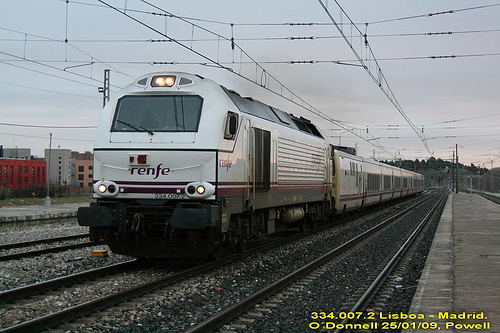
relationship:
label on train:
[126, 158, 171, 180] [72, 62, 433, 267]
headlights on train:
[181, 175, 211, 204] [72, 62, 433, 267]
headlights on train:
[93, 183, 121, 202] [72, 62, 433, 267]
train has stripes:
[72, 62, 433, 267] [218, 176, 255, 197]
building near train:
[40, 146, 77, 191] [72, 62, 433, 267]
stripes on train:
[218, 176, 255, 197] [72, 62, 433, 267]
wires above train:
[70, 18, 464, 73] [72, 62, 433, 267]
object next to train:
[82, 242, 112, 261] [72, 62, 433, 267]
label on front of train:
[126, 158, 171, 180] [72, 62, 433, 267]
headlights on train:
[146, 73, 174, 87] [72, 62, 433, 267]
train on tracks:
[72, 62, 433, 267] [20, 260, 170, 322]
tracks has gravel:
[20, 260, 170, 322] [75, 280, 119, 299]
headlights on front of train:
[146, 73, 174, 87] [72, 62, 433, 267]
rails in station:
[207, 180, 439, 324] [27, 66, 497, 324]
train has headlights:
[72, 62, 433, 267] [146, 73, 174, 87]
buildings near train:
[4, 136, 92, 194] [72, 62, 433, 267]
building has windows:
[40, 146, 77, 191] [52, 155, 66, 187]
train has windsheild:
[72, 62, 433, 267] [105, 93, 210, 139]